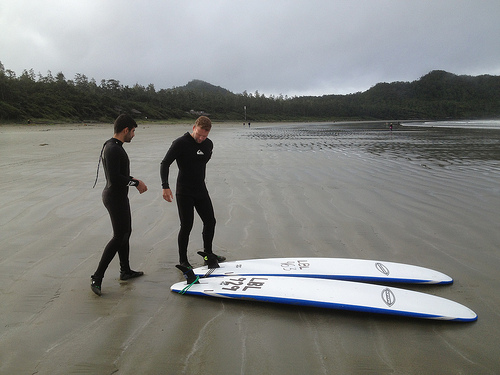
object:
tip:
[463, 306, 477, 322]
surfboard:
[168, 265, 478, 325]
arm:
[159, 142, 178, 190]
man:
[158, 114, 226, 276]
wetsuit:
[159, 130, 217, 263]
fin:
[174, 264, 201, 285]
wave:
[422, 120, 499, 126]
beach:
[0, 119, 500, 375]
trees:
[53, 71, 67, 85]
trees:
[108, 78, 120, 91]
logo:
[196, 149, 204, 155]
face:
[193, 129, 208, 144]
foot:
[89, 272, 104, 296]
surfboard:
[182, 251, 453, 287]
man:
[88, 111, 147, 298]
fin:
[196, 250, 220, 269]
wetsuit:
[92, 138, 139, 280]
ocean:
[399, 120, 499, 132]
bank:
[2, 104, 379, 127]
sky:
[0, 0, 499, 99]